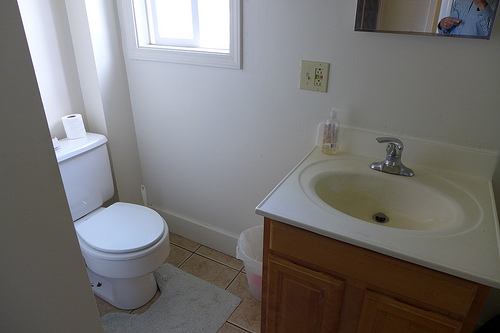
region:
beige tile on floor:
[169, 230, 199, 254]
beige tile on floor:
[164, 243, 189, 265]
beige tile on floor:
[192, 245, 240, 272]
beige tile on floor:
[178, 253, 236, 291]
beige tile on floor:
[225, 271, 256, 331]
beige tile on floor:
[217, 320, 248, 332]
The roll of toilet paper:
[60, 103, 92, 136]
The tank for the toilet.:
[51, 134, 134, 214]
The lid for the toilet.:
[81, 199, 165, 254]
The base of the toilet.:
[85, 272, 159, 310]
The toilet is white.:
[46, 115, 209, 311]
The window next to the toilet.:
[120, 3, 257, 85]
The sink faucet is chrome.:
[368, 132, 413, 177]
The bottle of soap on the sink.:
[309, 95, 353, 159]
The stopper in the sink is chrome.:
[368, 201, 391, 222]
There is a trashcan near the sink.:
[235, 220, 274, 296]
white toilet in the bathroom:
[47, 128, 174, 304]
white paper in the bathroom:
[58, 110, 85, 145]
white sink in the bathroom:
[306, 163, 465, 242]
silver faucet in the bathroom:
[370, 133, 417, 178]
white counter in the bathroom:
[257, 120, 499, 285]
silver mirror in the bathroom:
[356, 0, 497, 47]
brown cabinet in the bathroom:
[256, 219, 483, 331]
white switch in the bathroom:
[294, 58, 332, 97]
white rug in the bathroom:
[102, 263, 236, 331]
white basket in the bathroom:
[235, 224, 269, 304]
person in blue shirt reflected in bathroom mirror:
[432, 1, 498, 38]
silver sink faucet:
[365, 129, 422, 187]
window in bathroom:
[115, 2, 248, 76]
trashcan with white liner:
[225, 222, 265, 307]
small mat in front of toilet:
[98, 253, 246, 331]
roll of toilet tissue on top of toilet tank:
[59, 110, 89, 141]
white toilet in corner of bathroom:
[51, 129, 174, 314]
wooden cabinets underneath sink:
[249, 210, 496, 331]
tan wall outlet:
[292, 49, 337, 101]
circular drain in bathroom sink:
[367, 207, 397, 228]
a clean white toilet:
[51, 130, 171, 310]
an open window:
[130, 0, 228, 52]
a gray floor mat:
[99, 259, 242, 331]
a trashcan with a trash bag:
[236, 220, 262, 301]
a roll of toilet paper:
[61, 112, 86, 140]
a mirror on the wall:
[351, 0, 498, 40]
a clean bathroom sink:
[298, 155, 485, 240]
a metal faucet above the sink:
[368, 134, 414, 176]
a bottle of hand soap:
[321, 108, 343, 153]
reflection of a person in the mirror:
[436, 0, 496, 37]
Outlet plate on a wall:
[296, 60, 331, 92]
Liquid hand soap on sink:
[324, 109, 345, 154]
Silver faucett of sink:
[371, 133, 413, 174]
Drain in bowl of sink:
[370, 205, 395, 222]